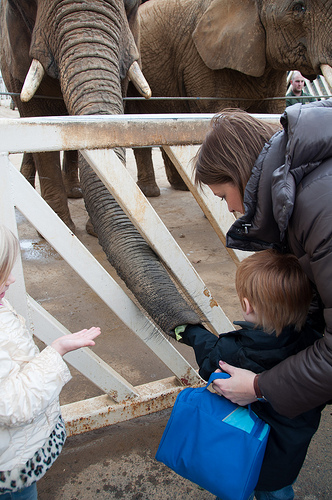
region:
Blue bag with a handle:
[152, 368, 270, 498]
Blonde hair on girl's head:
[0, 219, 23, 303]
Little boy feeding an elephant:
[163, 246, 323, 431]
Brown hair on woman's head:
[189, 107, 282, 218]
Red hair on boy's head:
[236, 243, 313, 338]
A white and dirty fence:
[0, 112, 288, 439]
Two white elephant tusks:
[18, 52, 155, 109]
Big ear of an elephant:
[189, 0, 269, 79]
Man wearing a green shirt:
[281, 69, 315, 105]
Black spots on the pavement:
[66, 439, 203, 497]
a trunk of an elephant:
[59, 53, 199, 347]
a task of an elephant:
[116, 47, 158, 99]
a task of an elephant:
[4, 51, 58, 116]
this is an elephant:
[6, 4, 210, 370]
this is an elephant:
[134, 3, 326, 116]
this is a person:
[2, 232, 100, 498]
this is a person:
[151, 263, 330, 496]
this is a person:
[182, 98, 328, 434]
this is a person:
[275, 58, 327, 121]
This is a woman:
[194, 99, 328, 429]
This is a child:
[183, 243, 316, 493]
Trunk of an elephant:
[69, 24, 235, 390]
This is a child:
[3, 215, 105, 491]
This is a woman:
[188, 85, 283, 232]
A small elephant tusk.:
[129, 61, 160, 105]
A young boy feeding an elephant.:
[182, 229, 321, 424]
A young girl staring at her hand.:
[2, 222, 101, 495]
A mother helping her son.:
[176, 95, 320, 419]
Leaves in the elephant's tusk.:
[169, 322, 189, 340]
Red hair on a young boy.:
[232, 248, 299, 334]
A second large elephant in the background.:
[148, 5, 330, 110]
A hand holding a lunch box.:
[163, 344, 265, 495]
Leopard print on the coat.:
[10, 449, 82, 490]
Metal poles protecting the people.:
[31, 212, 184, 440]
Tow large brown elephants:
[0, 0, 331, 118]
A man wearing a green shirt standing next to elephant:
[261, 2, 330, 101]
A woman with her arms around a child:
[195, 113, 330, 366]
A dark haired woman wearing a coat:
[202, 105, 331, 254]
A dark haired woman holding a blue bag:
[175, 97, 330, 498]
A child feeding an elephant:
[23, 34, 308, 375]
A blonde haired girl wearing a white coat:
[1, 228, 98, 412]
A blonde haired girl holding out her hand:
[0, 232, 109, 410]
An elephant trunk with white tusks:
[20, 46, 231, 498]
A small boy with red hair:
[235, 254, 324, 322]